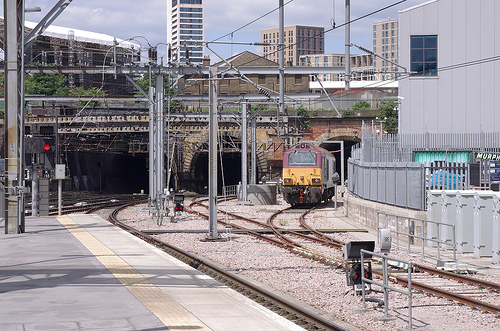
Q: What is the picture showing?
A: It is showing a railroad.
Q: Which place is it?
A: It is a railroad.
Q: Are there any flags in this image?
A: No, there are no flags.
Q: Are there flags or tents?
A: No, there are no flags or tents.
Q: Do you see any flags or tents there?
A: No, there are no flags or tents.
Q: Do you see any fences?
A: Yes, there is a fence.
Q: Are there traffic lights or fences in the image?
A: Yes, there is a fence.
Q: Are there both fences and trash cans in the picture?
A: No, there is a fence but no trash cans.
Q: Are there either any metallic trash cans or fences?
A: Yes, there is a metal fence.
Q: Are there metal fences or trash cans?
A: Yes, there is a metal fence.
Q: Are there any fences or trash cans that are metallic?
A: Yes, the fence is metallic.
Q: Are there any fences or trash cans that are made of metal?
A: Yes, the fence is made of metal.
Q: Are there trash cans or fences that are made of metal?
A: Yes, the fence is made of metal.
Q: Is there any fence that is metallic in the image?
A: Yes, there is a metal fence.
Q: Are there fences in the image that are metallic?
A: Yes, there is a fence that is metallic.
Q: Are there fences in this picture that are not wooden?
A: Yes, there is a metallic fence.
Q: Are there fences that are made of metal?
A: Yes, there is a fence that is made of metal.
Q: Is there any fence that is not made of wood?
A: Yes, there is a fence that is made of metal.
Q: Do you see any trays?
A: No, there are no trays.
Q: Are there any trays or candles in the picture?
A: No, there are no trays or candles.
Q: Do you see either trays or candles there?
A: No, there are no trays or candles.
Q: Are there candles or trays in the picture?
A: No, there are no trays or candles.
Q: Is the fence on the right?
A: Yes, the fence is on the right of the image.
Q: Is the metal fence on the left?
A: No, the fence is on the right of the image.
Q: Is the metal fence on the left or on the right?
A: The fence is on the right of the image.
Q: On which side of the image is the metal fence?
A: The fence is on the right of the image.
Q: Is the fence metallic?
A: Yes, the fence is metallic.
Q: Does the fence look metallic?
A: Yes, the fence is metallic.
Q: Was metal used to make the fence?
A: Yes, the fence is made of metal.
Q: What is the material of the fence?
A: The fence is made of metal.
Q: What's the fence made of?
A: The fence is made of metal.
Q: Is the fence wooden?
A: No, the fence is metallic.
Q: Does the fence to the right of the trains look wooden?
A: No, the fence is metallic.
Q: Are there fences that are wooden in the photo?
A: No, there is a fence but it is metallic.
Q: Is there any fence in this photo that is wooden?
A: No, there is a fence but it is metallic.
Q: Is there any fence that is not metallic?
A: No, there is a fence but it is metallic.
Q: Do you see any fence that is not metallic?
A: No, there is a fence but it is metallic.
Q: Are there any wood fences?
A: No, there is a fence but it is made of metal.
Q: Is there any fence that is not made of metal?
A: No, there is a fence but it is made of metal.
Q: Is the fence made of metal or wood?
A: The fence is made of metal.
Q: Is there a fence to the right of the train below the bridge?
A: Yes, there is a fence to the right of the train.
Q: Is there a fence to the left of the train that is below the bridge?
A: No, the fence is to the right of the train.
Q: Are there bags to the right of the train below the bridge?
A: No, there is a fence to the right of the train.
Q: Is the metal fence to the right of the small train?
A: Yes, the fence is to the right of the train.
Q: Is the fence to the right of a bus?
A: No, the fence is to the right of the train.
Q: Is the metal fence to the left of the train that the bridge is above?
A: No, the fence is to the right of the train.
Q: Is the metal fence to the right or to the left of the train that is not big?
A: The fence is to the right of the train.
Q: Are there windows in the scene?
A: Yes, there is a window.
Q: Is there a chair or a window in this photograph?
A: Yes, there is a window.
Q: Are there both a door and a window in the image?
A: No, there is a window but no doors.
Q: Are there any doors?
A: No, there are no doors.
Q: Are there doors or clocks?
A: No, there are no doors or clocks.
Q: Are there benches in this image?
A: No, there are no benches.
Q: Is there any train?
A: Yes, there is a train.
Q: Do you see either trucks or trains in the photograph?
A: Yes, there is a train.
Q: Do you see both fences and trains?
A: Yes, there are both a train and a fence.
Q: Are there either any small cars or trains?
A: Yes, there is a small train.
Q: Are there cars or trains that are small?
A: Yes, the train is small.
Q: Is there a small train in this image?
A: Yes, there is a small train.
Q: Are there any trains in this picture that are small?
A: Yes, there is a small train.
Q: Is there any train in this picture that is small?
A: Yes, there is a train that is small.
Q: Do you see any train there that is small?
A: Yes, there is a train that is small.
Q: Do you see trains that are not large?
A: Yes, there is a small train.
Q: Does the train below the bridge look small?
A: Yes, the train is small.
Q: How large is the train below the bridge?
A: The train is small.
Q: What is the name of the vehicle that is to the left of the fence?
A: The vehicle is a train.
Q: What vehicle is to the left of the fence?
A: The vehicle is a train.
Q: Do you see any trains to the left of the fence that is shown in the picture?
A: Yes, there is a train to the left of the fence.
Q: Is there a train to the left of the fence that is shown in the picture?
A: Yes, there is a train to the left of the fence.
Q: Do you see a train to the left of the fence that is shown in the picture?
A: Yes, there is a train to the left of the fence.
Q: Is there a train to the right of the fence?
A: No, the train is to the left of the fence.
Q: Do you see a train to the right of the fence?
A: No, the train is to the left of the fence.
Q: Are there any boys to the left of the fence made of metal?
A: No, there is a train to the left of the fence.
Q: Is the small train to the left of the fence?
A: Yes, the train is to the left of the fence.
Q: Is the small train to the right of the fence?
A: No, the train is to the left of the fence.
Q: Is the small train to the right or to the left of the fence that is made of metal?
A: The train is to the left of the fence.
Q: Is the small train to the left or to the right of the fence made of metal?
A: The train is to the left of the fence.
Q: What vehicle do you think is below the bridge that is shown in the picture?
A: The vehicle is a train.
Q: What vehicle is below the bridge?
A: The vehicle is a train.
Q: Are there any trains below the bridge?
A: Yes, there is a train below the bridge.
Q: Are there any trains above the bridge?
A: No, the train is below the bridge.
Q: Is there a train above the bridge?
A: No, the train is below the bridge.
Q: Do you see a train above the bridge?
A: No, the train is below the bridge.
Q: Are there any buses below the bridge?
A: No, there is a train below the bridge.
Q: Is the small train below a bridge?
A: Yes, the train is below a bridge.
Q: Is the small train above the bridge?
A: No, the train is below the bridge.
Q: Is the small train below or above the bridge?
A: The train is below the bridge.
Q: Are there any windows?
A: Yes, there is a window.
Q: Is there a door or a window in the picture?
A: Yes, there is a window.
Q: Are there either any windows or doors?
A: Yes, there is a window.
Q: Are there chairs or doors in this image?
A: No, there are no doors or chairs.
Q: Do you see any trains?
A: Yes, there are trains.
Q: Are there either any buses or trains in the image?
A: Yes, there are trains.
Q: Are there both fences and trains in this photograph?
A: Yes, there are both trains and a fence.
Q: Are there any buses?
A: No, there are no buses.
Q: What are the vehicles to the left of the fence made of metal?
A: The vehicles are trains.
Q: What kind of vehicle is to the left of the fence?
A: The vehicles are trains.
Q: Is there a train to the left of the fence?
A: Yes, there are trains to the left of the fence.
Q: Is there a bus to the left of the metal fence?
A: No, there are trains to the left of the fence.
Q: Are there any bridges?
A: Yes, there is a bridge.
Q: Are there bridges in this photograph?
A: Yes, there is a bridge.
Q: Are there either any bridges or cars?
A: Yes, there is a bridge.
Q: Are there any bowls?
A: No, there are no bowls.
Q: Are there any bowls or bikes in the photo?
A: No, there are no bowls or bikes.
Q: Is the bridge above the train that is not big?
A: Yes, the bridge is above the train.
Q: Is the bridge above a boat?
A: No, the bridge is above the train.